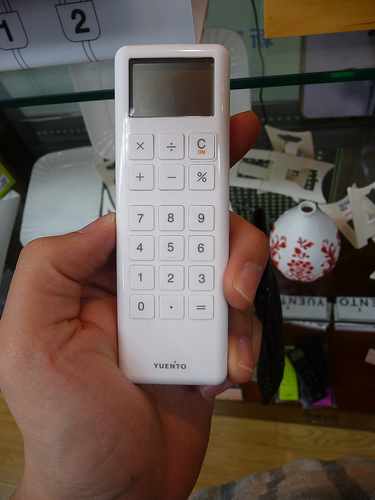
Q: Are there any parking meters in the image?
A: No, there are no parking meters.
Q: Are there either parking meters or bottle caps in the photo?
A: No, there are no parking meters or bottle caps.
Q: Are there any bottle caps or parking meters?
A: No, there are no parking meters or bottle caps.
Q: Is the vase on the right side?
A: Yes, the vase is on the right of the image.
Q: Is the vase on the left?
A: No, the vase is on the right of the image.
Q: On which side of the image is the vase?
A: The vase is on the right of the image.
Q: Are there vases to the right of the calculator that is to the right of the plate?
A: Yes, there is a vase to the right of the calculator.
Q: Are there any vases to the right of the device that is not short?
A: Yes, there is a vase to the right of the calculator.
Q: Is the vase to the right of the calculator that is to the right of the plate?
A: Yes, the vase is to the right of the calculator.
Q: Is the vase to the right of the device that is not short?
A: Yes, the vase is to the right of the calculator.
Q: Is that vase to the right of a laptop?
A: No, the vase is to the right of the calculator.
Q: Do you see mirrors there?
A: No, there are no mirrors.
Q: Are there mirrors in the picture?
A: No, there are no mirrors.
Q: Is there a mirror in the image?
A: No, there are no mirrors.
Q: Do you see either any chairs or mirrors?
A: No, there are no mirrors or chairs.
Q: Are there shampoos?
A: No, there are no shampoos.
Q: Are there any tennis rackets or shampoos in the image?
A: No, there are no shampoos or tennis rackets.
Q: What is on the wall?
A: The wire is on the wall.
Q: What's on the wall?
A: The wire is on the wall.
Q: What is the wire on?
A: The wire is on the wall.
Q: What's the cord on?
A: The wire is on the wall.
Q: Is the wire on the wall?
A: Yes, the wire is on the wall.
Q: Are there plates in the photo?
A: Yes, there is a plate.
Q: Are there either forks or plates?
A: Yes, there is a plate.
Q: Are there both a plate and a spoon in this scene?
A: No, there is a plate but no spoons.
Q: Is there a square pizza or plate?
A: Yes, there is a square plate.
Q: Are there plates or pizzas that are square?
A: Yes, the plate is square.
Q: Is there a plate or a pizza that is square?
A: Yes, the plate is square.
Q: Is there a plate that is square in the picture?
A: Yes, there is a square plate.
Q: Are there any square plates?
A: Yes, there is a square plate.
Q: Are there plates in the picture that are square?
A: Yes, there is a plate that is square.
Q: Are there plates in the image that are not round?
A: Yes, there is a square plate.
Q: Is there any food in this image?
A: No, there is no food.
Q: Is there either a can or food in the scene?
A: No, there are no food or cans.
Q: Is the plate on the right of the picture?
A: No, the plate is on the left of the image.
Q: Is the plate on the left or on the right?
A: The plate is on the left of the image.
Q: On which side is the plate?
A: The plate is on the left of the image.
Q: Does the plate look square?
A: Yes, the plate is square.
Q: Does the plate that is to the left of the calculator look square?
A: Yes, the plate is square.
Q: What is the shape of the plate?
A: The plate is square.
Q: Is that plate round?
A: No, the plate is square.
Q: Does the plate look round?
A: No, the plate is square.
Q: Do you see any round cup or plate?
A: No, there is a plate but it is square.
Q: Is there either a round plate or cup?
A: No, there is a plate but it is square.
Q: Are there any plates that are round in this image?
A: No, there is a plate but it is square.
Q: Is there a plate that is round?
A: No, there is a plate but it is square.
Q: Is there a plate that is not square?
A: No, there is a plate but it is square.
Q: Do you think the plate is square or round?
A: The plate is square.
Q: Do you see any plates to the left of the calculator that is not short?
A: Yes, there is a plate to the left of the calculator.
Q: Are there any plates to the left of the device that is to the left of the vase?
A: Yes, there is a plate to the left of the calculator.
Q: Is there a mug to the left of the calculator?
A: No, there is a plate to the left of the calculator.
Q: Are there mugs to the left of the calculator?
A: No, there is a plate to the left of the calculator.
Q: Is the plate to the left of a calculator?
A: Yes, the plate is to the left of a calculator.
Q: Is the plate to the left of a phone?
A: No, the plate is to the left of a calculator.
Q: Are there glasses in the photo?
A: No, there are no glasses.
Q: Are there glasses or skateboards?
A: No, there are no glasses or skateboards.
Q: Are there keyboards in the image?
A: No, there are no keyboards.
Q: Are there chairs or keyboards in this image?
A: No, there are no keyboards or chairs.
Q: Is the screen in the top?
A: Yes, the screen is in the top of the image.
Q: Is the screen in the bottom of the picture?
A: No, the screen is in the top of the image.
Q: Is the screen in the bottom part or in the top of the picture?
A: The screen is in the top of the image.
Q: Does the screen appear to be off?
A: Yes, the screen is off.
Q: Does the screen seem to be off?
A: Yes, the screen is off.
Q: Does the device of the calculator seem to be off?
A: Yes, the screen is off.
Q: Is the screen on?
A: No, the screen is off.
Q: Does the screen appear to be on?
A: No, the screen is off.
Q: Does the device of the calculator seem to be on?
A: No, the screen is off.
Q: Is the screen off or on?
A: The screen is off.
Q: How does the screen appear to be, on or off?
A: The screen is off.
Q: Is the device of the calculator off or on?
A: The screen is off.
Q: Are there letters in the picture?
A: Yes, there are letters.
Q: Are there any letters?
A: Yes, there are letters.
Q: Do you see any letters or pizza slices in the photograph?
A: Yes, there are letters.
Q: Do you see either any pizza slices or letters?
A: Yes, there are letters.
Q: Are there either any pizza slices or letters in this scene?
A: Yes, there are letters.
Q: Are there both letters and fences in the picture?
A: No, there are letters but no fences.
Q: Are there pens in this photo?
A: No, there are no pens.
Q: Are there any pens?
A: No, there are no pens.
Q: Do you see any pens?
A: No, there are no pens.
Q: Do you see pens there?
A: No, there are no pens.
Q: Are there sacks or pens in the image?
A: No, there are no pens or sacks.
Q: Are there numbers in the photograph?
A: Yes, there are numbers.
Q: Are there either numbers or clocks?
A: Yes, there are numbers.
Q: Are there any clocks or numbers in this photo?
A: Yes, there are numbers.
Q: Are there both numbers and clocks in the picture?
A: No, there are numbers but no clocks.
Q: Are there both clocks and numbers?
A: No, there are numbers but no clocks.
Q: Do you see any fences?
A: No, there are no fences.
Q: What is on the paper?
A: The numbers are on the paper.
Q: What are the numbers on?
A: The numbers are on the paper.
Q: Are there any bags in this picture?
A: No, there are no bags.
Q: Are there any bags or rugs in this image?
A: No, there are no bags or rugs.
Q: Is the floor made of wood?
A: Yes, the floor is made of wood.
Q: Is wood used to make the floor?
A: Yes, the floor is made of wood.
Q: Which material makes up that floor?
A: The floor is made of wood.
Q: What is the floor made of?
A: The floor is made of wood.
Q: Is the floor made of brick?
A: No, the floor is made of wood.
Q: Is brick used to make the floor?
A: No, the floor is made of wood.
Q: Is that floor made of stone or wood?
A: The floor is made of wood.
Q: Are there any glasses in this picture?
A: No, there are no glasses.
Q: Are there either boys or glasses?
A: No, there are no glasses or boys.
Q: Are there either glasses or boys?
A: No, there are no glasses or boys.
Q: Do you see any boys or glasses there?
A: No, there are no glasses or boys.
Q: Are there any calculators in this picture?
A: Yes, there is a calculator.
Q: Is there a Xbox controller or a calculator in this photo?
A: Yes, there is a calculator.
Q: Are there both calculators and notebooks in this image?
A: No, there is a calculator but no notebooks.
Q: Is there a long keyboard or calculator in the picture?
A: Yes, there is a long calculator.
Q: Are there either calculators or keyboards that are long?
A: Yes, the calculator is long.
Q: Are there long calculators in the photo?
A: Yes, there is a long calculator.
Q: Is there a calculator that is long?
A: Yes, there is a long calculator.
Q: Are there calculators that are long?
A: Yes, there is a calculator that is long.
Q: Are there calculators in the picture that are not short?
A: Yes, there is a long calculator.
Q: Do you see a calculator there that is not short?
A: Yes, there is a long calculator.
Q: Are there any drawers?
A: No, there are no drawers.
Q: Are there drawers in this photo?
A: No, there are no drawers.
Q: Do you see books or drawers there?
A: No, there are no drawers or books.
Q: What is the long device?
A: The device is a calculator.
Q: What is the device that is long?
A: The device is a calculator.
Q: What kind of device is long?
A: The device is a calculator.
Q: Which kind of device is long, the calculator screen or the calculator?
A: The calculator is long.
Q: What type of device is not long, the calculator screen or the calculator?
A: The screen is not long.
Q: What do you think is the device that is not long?
A: The device is a screen.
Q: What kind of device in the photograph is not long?
A: The device is a screen.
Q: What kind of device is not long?
A: The device is a screen.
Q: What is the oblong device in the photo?
A: The device is a calculator.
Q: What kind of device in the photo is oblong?
A: The device is a calculator.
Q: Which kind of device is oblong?
A: The device is a calculator.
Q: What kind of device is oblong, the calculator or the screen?
A: The calculator is oblong.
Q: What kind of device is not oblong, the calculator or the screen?
A: The screen is not oblong.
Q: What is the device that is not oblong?
A: The device is a screen.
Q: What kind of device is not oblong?
A: The device is a screen.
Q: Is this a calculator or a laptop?
A: This is a calculator.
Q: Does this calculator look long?
A: Yes, the calculator is long.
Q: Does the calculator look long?
A: Yes, the calculator is long.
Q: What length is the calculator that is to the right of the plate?
A: The calculator is long.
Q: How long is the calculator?
A: The calculator is long.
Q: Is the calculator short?
A: No, the calculator is long.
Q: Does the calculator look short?
A: No, the calculator is long.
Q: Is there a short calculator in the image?
A: No, there is a calculator but it is long.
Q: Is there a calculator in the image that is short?
A: No, there is a calculator but it is long.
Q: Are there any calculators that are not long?
A: No, there is a calculator but it is long.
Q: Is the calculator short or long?
A: The calculator is long.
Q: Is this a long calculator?
A: Yes, this is a long calculator.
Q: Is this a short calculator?
A: No, this is a long calculator.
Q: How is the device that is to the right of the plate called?
A: The device is a calculator.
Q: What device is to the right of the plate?
A: The device is a calculator.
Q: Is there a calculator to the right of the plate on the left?
A: Yes, there is a calculator to the right of the plate.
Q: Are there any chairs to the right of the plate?
A: No, there is a calculator to the right of the plate.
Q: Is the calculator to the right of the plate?
A: Yes, the calculator is to the right of the plate.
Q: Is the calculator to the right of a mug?
A: No, the calculator is to the right of the plate.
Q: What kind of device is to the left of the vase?
A: The device is a calculator.